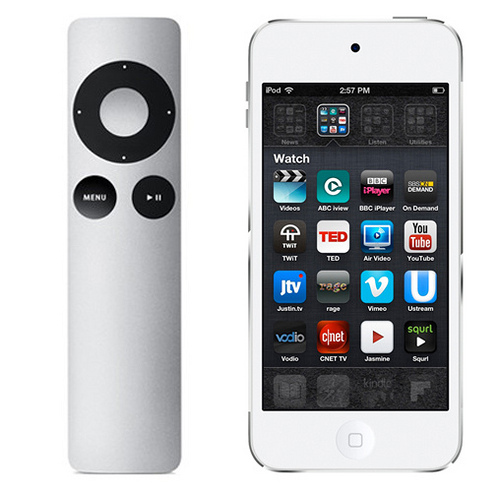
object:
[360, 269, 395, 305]
vimeo button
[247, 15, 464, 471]
ipod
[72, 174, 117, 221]
menu button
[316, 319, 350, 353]
button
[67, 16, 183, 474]
remote control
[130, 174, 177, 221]
button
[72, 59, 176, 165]
directional button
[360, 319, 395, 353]
button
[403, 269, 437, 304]
button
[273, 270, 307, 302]
button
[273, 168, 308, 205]
button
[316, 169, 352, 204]
button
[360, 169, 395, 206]
button